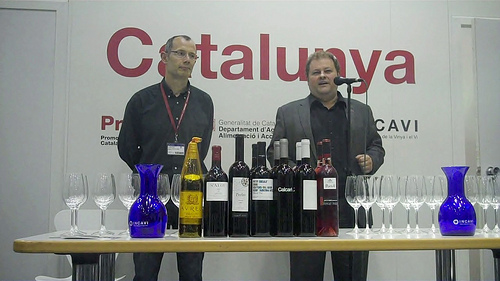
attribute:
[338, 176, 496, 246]
glasses — empty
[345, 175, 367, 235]
wine glass — empty 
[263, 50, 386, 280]
man — standing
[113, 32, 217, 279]
man — standing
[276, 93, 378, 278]
suit — grey, black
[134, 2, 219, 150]
man — tall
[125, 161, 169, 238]
vase — blue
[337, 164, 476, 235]
glasses — empty, wine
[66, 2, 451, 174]
catalunya sign — red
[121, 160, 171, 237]
vase — blue 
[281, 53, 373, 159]
man — short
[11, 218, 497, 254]
table — long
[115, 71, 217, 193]
shirt — black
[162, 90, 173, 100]
buttons — white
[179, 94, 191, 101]
buttons — white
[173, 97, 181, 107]
buttons — white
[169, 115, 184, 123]
buttons — white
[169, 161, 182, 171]
buttons — white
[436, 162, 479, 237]
vase — blue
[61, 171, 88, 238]
glass — empty 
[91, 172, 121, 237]
glass — empty 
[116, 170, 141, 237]
glass — empty 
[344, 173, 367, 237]
glass — empty 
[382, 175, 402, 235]
glass — empty 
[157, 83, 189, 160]
lanyard — Red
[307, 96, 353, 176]
shirt — black